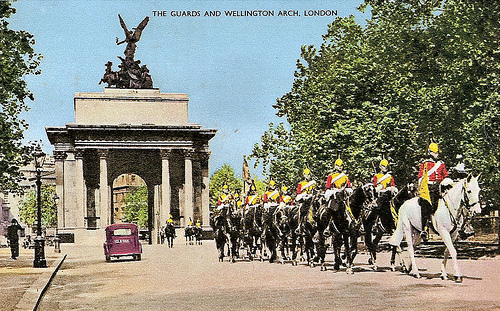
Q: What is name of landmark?
A: Wellington Arch.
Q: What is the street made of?
A: Dirt.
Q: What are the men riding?
A: Horses.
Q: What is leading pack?
A: White horse.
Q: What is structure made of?
A: Stone.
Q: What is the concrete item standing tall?
A: A building.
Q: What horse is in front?
A: A white horse.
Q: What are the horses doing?
A: Moving.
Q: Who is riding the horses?
A: Guards.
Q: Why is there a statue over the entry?
A: Decoration.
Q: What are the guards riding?
A: Horses.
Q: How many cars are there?
A: One.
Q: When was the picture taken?
A: Daytime.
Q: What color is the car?
A: Purple.